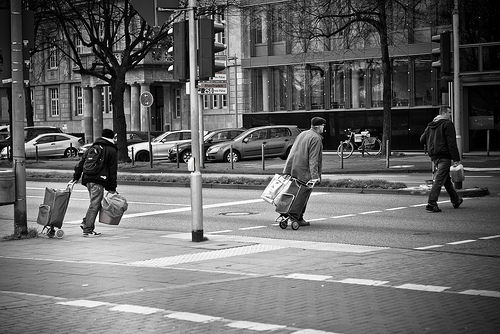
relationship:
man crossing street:
[71, 127, 121, 237] [155, 225, 375, 299]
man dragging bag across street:
[280, 170, 317, 232] [155, 225, 375, 299]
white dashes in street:
[278, 237, 487, 309] [155, 225, 375, 299]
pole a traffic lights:
[187, 0, 204, 244] [165, 17, 227, 83]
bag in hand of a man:
[81, 170, 132, 240] [75, 93, 138, 282]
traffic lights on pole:
[167, 17, 227, 80] [190, 1, 200, 265]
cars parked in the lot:
[43, 133, 280, 163] [42, 111, 324, 178]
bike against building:
[341, 104, 398, 192] [235, 12, 433, 155]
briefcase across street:
[37, 178, 79, 240] [155, 225, 375, 299]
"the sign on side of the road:
[141, 72, 154, 121] [130, 137, 185, 290]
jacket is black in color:
[59, 131, 136, 203] [75, 93, 138, 282]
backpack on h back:
[83, 145, 106, 176] [87, 130, 120, 196]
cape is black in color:
[104, 112, 136, 154] [269, 101, 345, 280]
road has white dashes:
[144, 130, 350, 308] [278, 272, 500, 300]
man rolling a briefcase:
[75, 93, 138, 282] [39, 179, 89, 265]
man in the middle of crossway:
[280, 66, 360, 283] [398, 131, 443, 279]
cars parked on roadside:
[43, 133, 280, 163] [203, 80, 472, 148]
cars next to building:
[43, 133, 280, 163] [235, 12, 433, 155]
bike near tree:
[341, 104, 398, 192] [357, 10, 399, 181]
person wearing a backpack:
[75, 93, 138, 282] [88, 138, 110, 186]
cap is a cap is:
[310, 116, 326, 126] [310, 116, 326, 126]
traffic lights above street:
[167, 17, 227, 80] [155, 225, 375, 299]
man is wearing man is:
[427, 156, 464, 223] [425, 159, 463, 205]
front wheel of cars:
[121, 121, 271, 172] [43, 133, 280, 163]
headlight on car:
[194, 140, 225, 162] [204, 106, 325, 193]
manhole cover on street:
[217, 179, 261, 249] [155, 225, 375, 299]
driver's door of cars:
[237, 118, 289, 176] [43, 133, 280, 163]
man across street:
[71, 127, 121, 237] [155, 225, 375, 299]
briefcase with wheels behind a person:
[37, 178, 79, 240] [75, 93, 138, 282]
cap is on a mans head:
[310, 108, 332, 128] [301, 75, 342, 177]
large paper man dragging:
[172, 72, 378, 264] [275, 180, 319, 231]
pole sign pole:
[187, 0, 204, 244] [190, 1, 200, 265]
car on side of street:
[206, 125, 303, 163] [155, 225, 375, 299]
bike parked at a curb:
[341, 104, 398, 192] [340, 117, 448, 169]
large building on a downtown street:
[235, 12, 433, 155] [155, 225, 375, 299]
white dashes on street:
[278, 237, 487, 309] [155, 225, 375, 299]